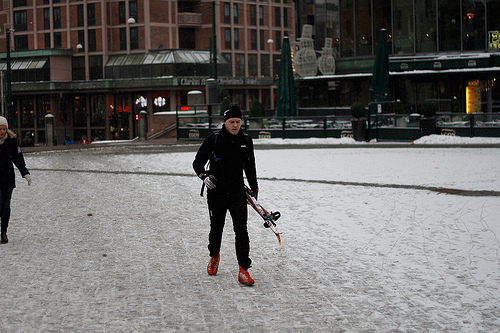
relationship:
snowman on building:
[294, 21, 322, 78] [0, 0, 497, 142]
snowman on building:
[316, 30, 337, 78] [0, 0, 497, 142]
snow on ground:
[5, 135, 497, 330] [0, 131, 498, 331]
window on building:
[218, 4, 242, 26] [5, 0, 301, 132]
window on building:
[251, 5, 265, 25] [5, 0, 301, 132]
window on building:
[272, 7, 292, 27] [5, 0, 301, 132]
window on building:
[220, 29, 244, 51] [5, 0, 301, 132]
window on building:
[246, 28, 266, 48] [5, 0, 301, 132]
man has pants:
[191, 108, 262, 288] [205, 189, 252, 269]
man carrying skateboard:
[191, 108, 262, 288] [221, 178, 332, 238]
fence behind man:
[281, 103, 340, 130] [191, 108, 262, 288]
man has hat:
[191, 108, 262, 288] [220, 104, 245, 119]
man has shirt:
[191, 108, 262, 288] [195, 129, 267, 203]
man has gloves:
[191, 108, 262, 288] [195, 174, 210, 191]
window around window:
[249, 29, 259, 52] [222, 26, 232, 51]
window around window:
[256, 2, 266, 23] [222, 26, 232, 51]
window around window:
[115, 25, 128, 52] [222, 26, 232, 51]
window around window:
[85, 25, 97, 52] [222, 26, 232, 51]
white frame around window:
[217, 18, 250, 53] [222, 26, 232, 51]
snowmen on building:
[293, 18, 336, 77] [279, 1, 497, 128]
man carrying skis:
[191, 108, 262, 288] [245, 182, 284, 242]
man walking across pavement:
[191, 108, 262, 288] [95, 147, 432, 332]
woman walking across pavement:
[0, 114, 33, 241] [101, 222, 225, 329]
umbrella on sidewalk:
[267, 31, 303, 136] [86, 186, 221, 331]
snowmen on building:
[293, 18, 318, 78] [288, 4, 498, 123]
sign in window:
[176, 102, 211, 114] [66, 84, 115, 145]